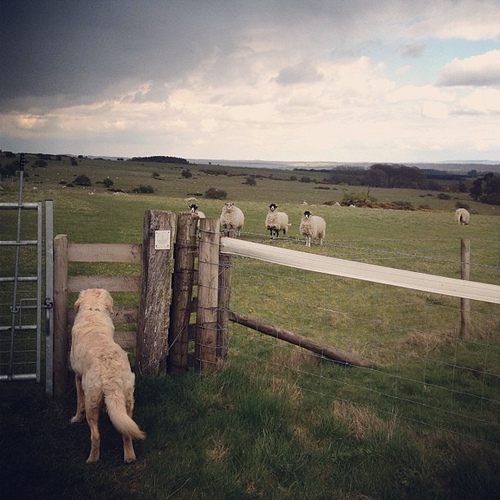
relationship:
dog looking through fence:
[70, 288, 147, 464] [0, 167, 500, 444]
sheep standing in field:
[198, 190, 479, 262] [33, 166, 484, 448]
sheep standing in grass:
[188, 202, 472, 247] [41, 152, 478, 396]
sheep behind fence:
[188, 202, 472, 247] [50, 204, 499, 448]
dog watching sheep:
[66, 273, 151, 465] [299, 207, 329, 244]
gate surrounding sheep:
[218, 221, 493, 461] [199, 185, 472, 238]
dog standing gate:
[70, 288, 147, 464] [10, 200, 482, 408]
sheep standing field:
[188, 202, 472, 247] [14, 145, 484, 307]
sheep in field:
[188, 202, 472, 247] [14, 153, 484, 419]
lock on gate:
[48, 300, 58, 330] [5, 193, 235, 394]